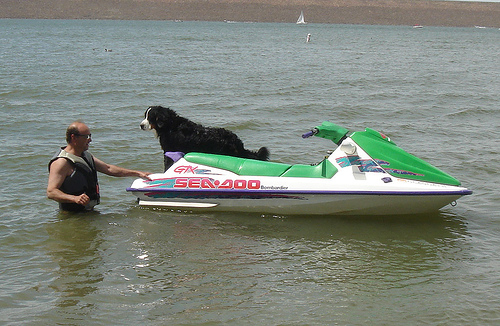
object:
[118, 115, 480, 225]
ski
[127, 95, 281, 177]
dog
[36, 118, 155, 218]
man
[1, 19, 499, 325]
lake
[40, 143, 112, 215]
lifejacket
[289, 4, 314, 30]
boat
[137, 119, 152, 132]
nose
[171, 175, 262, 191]
lettering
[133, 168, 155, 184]
hand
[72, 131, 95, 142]
glasses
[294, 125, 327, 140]
bar